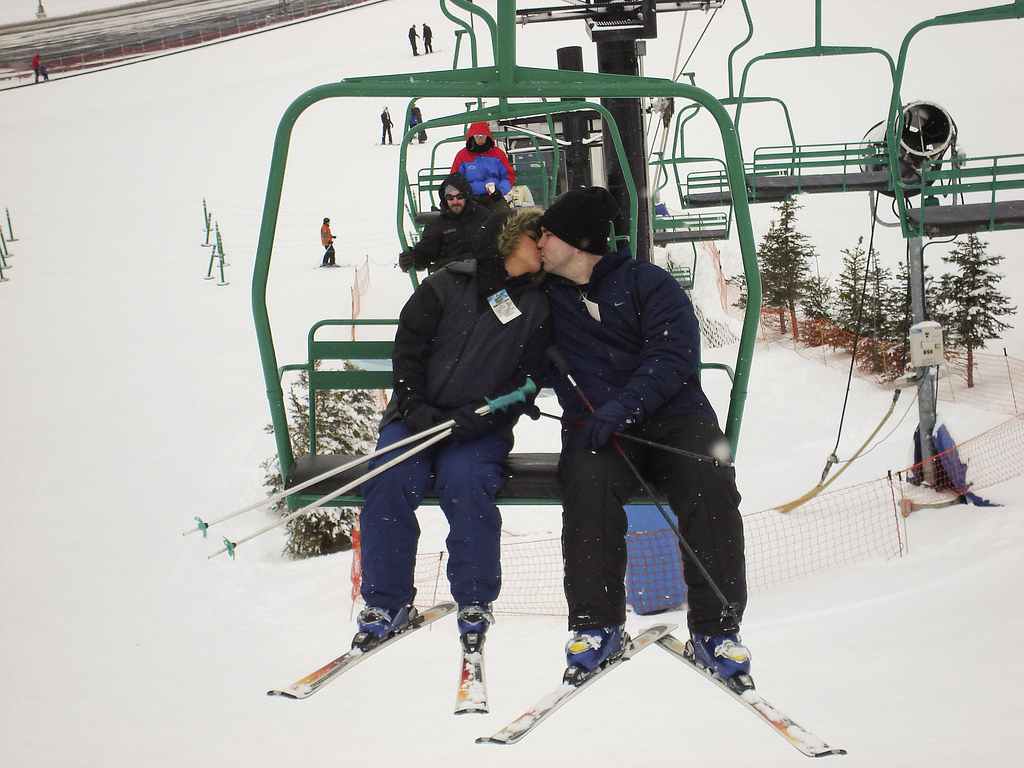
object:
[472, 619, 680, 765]
skis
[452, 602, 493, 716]
skis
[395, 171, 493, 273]
black coat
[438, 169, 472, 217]
black hood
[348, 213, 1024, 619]
orange fence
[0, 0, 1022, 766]
snow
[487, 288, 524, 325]
sticker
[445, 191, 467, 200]
sunglasses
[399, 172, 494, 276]
man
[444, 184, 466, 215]
face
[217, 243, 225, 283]
pole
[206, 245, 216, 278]
pole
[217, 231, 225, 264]
pole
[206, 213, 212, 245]
pole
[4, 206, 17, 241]
pole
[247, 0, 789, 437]
snow lift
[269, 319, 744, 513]
bench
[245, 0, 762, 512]
snow lift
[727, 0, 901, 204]
snow lift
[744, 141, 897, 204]
bench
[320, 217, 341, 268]
person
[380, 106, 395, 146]
people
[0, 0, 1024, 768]
hill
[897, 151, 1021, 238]
chair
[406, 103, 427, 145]
person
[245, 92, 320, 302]
slope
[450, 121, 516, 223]
person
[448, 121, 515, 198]
jacket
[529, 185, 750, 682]
guy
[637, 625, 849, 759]
skis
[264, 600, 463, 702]
skis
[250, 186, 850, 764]
couple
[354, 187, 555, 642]
girl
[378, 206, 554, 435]
jacket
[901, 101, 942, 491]
pole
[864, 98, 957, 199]
thing